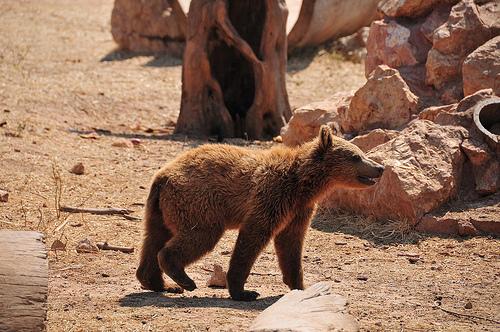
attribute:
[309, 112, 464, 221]
rock — large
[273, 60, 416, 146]
rock — large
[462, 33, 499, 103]
rock — large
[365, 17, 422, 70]
rock — large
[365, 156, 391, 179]
bear — young, nose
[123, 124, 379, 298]
bear — young, front paw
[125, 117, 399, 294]
bear — brown, walking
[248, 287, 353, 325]
wood — piece, sitting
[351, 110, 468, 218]
rocks — red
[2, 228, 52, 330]
log — large, brown, round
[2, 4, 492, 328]
ground — dirt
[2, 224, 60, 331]
log — large, wooden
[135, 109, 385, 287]
bear — big, brown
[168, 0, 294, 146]
stump — large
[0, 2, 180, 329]
sticks — large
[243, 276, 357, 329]
log — round, brown, large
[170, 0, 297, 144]
trunk — large, round, brown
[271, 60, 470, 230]
rock — brown, large, dirty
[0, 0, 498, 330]
floor — large, dirt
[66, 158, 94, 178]
rock — small, brown, round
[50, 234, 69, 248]
rock — round, small, brown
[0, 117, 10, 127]
rock — brown, small, round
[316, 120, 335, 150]
ear — small, furry, brown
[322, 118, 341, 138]
ear — brown, furry, small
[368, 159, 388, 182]
nose — small, round, black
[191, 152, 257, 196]
fur — brown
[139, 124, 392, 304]
bear — shadow, ground, brown, lone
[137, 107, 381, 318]
bear — young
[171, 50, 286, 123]
tree — old, hollowed-out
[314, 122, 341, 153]
ears — young bear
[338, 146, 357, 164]
eye — young bear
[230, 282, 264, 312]
bear — young,  back foot 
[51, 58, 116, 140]
dirt — ground 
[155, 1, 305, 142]
treestump — hollow 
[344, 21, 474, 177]
rock —  rock pile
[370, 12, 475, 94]
rock —  rock pile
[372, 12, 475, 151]
rock —  rock pile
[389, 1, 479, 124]
rock —  rock pile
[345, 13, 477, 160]
rock —  rock pile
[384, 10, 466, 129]
rock —  rock pile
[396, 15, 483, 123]
rock —  rock pile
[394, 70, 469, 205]
rock —  rock pile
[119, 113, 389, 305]
bear — small, furry, brown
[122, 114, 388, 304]
cub — brown